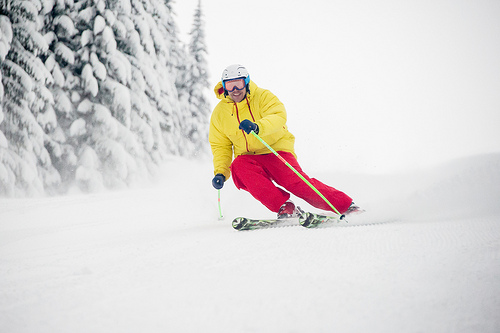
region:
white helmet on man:
[218, 60, 263, 92]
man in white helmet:
[219, 65, 256, 109]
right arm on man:
[205, 126, 247, 171]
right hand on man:
[206, 177, 226, 190]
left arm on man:
[262, 93, 289, 144]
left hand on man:
[235, 117, 271, 158]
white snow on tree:
[86, 100, 106, 122]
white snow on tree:
[102, 77, 150, 127]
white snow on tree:
[143, 66, 165, 98]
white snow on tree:
[141, 123, 169, 158]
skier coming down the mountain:
[195, 67, 363, 226]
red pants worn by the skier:
[228, 153, 348, 214]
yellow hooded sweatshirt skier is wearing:
[208, 83, 295, 162]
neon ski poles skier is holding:
[204, 136, 355, 226]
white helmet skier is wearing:
[220, 66, 257, 81]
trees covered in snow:
[2, 3, 224, 193]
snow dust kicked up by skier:
[139, 141, 283, 223]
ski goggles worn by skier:
[221, 75, 248, 92]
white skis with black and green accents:
[233, 210, 410, 230]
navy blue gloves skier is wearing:
[213, 118, 257, 185]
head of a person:
[213, 60, 257, 113]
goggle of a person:
[222, 75, 251, 90]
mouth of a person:
[219, 88, 249, 102]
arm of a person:
[204, 116, 240, 178]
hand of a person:
[206, 169, 229, 196]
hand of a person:
[235, 112, 260, 145]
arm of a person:
[247, 114, 289, 146]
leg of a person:
[238, 160, 270, 214]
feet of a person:
[292, 208, 326, 221]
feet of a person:
[332, 186, 367, 229]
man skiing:
[189, 52, 316, 205]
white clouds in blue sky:
[403, 32, 443, 71]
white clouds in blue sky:
[326, 28, 361, 62]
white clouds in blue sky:
[225, 13, 260, 49]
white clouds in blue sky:
[288, 10, 325, 40]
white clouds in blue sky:
[340, 103, 357, 122]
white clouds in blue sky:
[319, 79, 366, 121]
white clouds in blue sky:
[441, 55, 498, 83]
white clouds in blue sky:
[309, 60, 358, 123]